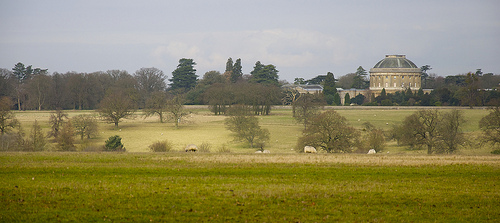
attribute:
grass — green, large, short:
[1, 145, 499, 219]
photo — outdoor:
[1, 1, 499, 222]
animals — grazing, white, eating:
[366, 147, 379, 156]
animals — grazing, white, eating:
[302, 142, 318, 155]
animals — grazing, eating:
[183, 147, 202, 154]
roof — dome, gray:
[369, 52, 417, 72]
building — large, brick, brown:
[363, 46, 427, 102]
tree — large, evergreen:
[166, 57, 202, 99]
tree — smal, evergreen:
[103, 133, 130, 156]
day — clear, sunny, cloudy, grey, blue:
[1, 2, 500, 96]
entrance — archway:
[338, 86, 361, 106]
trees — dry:
[291, 86, 336, 130]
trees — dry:
[64, 113, 100, 145]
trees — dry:
[94, 75, 141, 131]